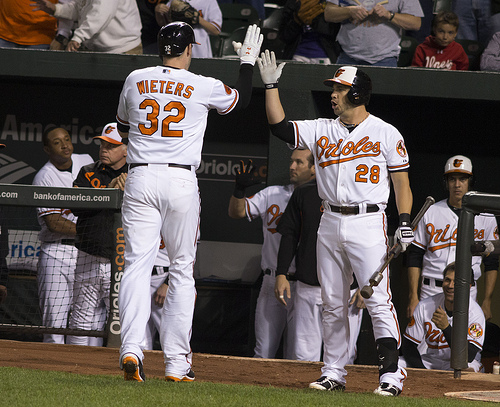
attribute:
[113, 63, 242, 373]
uniform — white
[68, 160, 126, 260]
jacket — black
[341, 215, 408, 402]
leg — black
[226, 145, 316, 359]
player — baseball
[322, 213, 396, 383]
pant — white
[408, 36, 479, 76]
sweatshirt — red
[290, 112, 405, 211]
jersey — white, orange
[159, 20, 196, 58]
helmet — black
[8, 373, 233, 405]
grass — green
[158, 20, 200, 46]
helmet — black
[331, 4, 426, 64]
shirt — grey